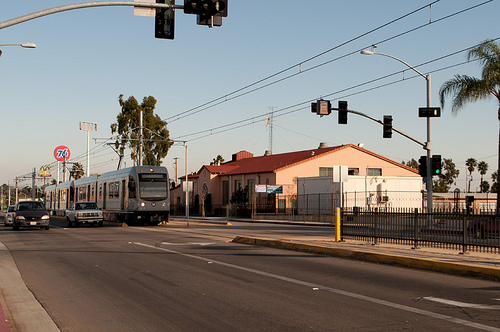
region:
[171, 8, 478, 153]
electrical wires over street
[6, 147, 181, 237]
train and cars stopped at stop light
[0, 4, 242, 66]
stop lights over street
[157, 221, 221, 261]
white arrow painted on street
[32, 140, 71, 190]
signs for businesses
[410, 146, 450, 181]
street light with the green light lit up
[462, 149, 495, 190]
tall palm trees in the distance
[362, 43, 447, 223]
modern street light over street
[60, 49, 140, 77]
light blue sky with no clouds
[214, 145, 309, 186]
red clay roof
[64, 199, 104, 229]
White pickup truck on a road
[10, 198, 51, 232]
Van driving on a road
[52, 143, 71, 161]
Orange sign with a blue seventy six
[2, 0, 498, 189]
Four power lines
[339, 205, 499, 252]
Rusted iron gate in the middle of a boulevard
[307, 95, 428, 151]
Traffic lights at an intersection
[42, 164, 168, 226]
Silver train operating on a track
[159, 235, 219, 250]
Directional white arrow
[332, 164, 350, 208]
Back of a street sign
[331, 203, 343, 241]
Reflective yellow pole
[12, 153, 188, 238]
a train in traffic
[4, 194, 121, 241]
cars next to the train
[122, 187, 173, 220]
a headlight is on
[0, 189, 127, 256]
the cars are driving down the street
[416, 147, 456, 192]
the light is green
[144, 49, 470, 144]
wires above the street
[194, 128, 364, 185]
the roof is red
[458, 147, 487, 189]
palm trees in the background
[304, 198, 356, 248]
a yellow pole in the background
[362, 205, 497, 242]
the fence is black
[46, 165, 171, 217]
grey tolly cars on street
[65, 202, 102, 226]
pickup truck on street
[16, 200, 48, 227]
black van on street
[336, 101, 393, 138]
black electronic stop light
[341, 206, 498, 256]
black iron fence on sidewalk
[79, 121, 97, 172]
grey metal lamp post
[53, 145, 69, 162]
orange and blue sign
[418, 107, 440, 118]
walk and don't walk sign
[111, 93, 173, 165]
tree with green leaves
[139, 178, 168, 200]
glass wind shield on trolly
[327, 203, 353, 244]
A yellow metal safety pole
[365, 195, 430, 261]
A metal fence along a road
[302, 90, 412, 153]
Stoplights on a traffic pole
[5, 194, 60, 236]
A dark car driving forward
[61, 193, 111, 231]
A white truck driving forward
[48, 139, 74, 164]
A 76 gasoline station sign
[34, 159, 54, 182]
A McDonald's restaurant sign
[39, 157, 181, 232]
A street car traveling down the tracks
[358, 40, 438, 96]
A street light on top of a pole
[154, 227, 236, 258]
A white turn sign painted on road